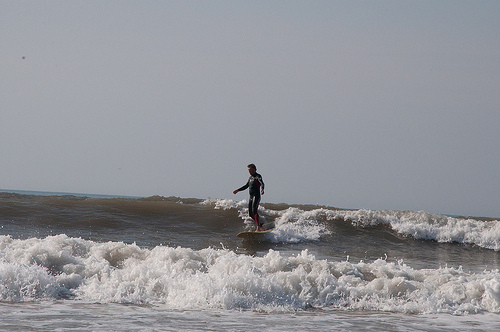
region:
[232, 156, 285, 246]
a surfer on a surfboard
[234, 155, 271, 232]
a surfer wearing a black and white surf outfit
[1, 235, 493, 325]
a wave in the ocean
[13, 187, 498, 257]
a wave in the ocean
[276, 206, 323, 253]
wake from a surfer on a surfboard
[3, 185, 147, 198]
clear blue ocean water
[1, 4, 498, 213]
clear blue skies with no clouds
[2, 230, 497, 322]
white ocean water from a wave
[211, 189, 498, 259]
white ocean water from a wave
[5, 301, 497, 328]
white foam from a wave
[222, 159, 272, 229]
man surfing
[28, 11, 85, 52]
white clouds in blue sky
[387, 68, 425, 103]
white clouds in blue sky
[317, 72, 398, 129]
white clouds in blue sky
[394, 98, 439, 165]
white clouds in blue sky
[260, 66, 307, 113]
white clouds in blue sky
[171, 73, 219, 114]
white clouds in blue sky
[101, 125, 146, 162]
white clouds in blue sky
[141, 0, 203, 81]
white clouds in blue sky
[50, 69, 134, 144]
white clouds in blue sky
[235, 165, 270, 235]
man on a surfboard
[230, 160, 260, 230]
a man wearing a back wetsuit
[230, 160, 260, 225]
a man with black hair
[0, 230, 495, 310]
a wave washing toward the shore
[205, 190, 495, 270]
wave pushing the surfboard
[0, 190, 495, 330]
gray colored water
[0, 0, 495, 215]
a gray blue colored sky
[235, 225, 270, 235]
a white colored surfboard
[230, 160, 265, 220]
the man has his arms out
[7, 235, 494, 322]
white foam on the water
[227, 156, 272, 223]
man standing on surfboard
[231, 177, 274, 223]
man wearing black wetsuit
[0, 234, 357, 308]
waves crashing against ocean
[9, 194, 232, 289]
large ocean waves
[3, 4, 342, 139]
gloomy sky during the day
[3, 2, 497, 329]
dark day at the beach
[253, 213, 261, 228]
red on the surfer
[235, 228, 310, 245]
white surfboard in ocean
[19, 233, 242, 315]
white foam in the ocean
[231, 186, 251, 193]
arm of a man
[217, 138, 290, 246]
The man is standing.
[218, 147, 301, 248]
The man is on a surfboard.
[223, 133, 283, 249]
The man is wearing a wetsuit.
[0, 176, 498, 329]
The water is wavy.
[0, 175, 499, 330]
The water is splashing.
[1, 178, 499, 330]
The water is turbulent.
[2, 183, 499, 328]
The water is powerful.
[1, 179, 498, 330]
The water is choppy.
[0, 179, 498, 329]
The water is zealous.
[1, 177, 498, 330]
The water is persistent.